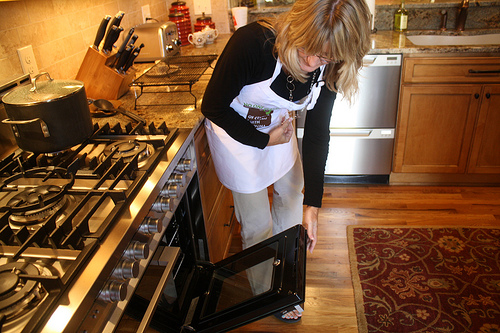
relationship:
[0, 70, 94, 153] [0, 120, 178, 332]
cooking pot on stove top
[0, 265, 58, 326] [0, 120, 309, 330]
burner of oven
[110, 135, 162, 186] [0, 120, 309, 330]
burner of oven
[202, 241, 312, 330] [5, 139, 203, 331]
door of oven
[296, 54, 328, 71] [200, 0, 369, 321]
nose person of woman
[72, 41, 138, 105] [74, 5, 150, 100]
holder with knives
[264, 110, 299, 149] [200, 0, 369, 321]
hand of woman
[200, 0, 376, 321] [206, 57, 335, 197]
woman wearing apron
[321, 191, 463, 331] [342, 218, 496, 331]
rug on floor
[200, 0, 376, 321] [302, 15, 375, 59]
woman with blonde hair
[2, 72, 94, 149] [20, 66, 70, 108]
pot with lid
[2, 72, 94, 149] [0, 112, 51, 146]
pot with handles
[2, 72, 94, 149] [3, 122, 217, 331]
pot sitting on stove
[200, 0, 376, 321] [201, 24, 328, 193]
woman wearing apron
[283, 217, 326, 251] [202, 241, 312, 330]
hand on door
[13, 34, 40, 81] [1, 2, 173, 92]
outlet on wall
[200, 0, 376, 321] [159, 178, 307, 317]
woman looking into oven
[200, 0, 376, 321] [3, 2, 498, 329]
woman in kitchen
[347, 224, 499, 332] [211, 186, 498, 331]
rug on floor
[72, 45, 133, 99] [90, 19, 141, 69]
holder for knife set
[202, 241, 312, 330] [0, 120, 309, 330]
door to oven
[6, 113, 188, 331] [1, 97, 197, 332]
grates on stovetop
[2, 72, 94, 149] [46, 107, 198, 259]
pot on stove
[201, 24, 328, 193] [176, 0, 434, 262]
apron on woman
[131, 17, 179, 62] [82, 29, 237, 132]
toaster on counter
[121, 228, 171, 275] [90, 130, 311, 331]
knob on oven